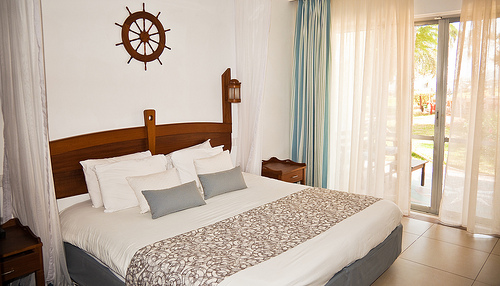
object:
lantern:
[225, 76, 242, 102]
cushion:
[142, 181, 209, 219]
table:
[0, 216, 46, 285]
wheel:
[114, 3, 173, 70]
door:
[413, 15, 441, 211]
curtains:
[328, 1, 413, 217]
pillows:
[195, 166, 250, 199]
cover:
[50, 170, 401, 286]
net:
[235, 0, 259, 176]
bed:
[47, 69, 411, 285]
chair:
[410, 160, 428, 187]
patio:
[407, 172, 500, 223]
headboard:
[44, 67, 234, 199]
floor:
[366, 209, 499, 285]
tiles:
[394, 234, 490, 280]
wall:
[41, 0, 240, 141]